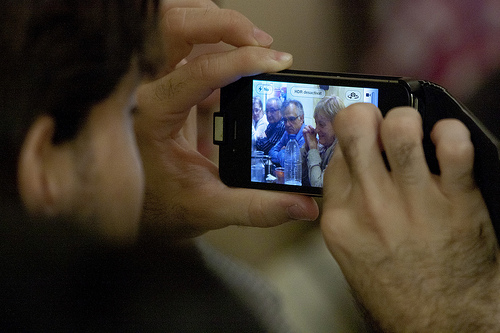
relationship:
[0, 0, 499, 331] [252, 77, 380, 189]
man looking at a picture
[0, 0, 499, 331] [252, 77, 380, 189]
man examining a picture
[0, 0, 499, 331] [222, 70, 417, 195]
man using cell phone